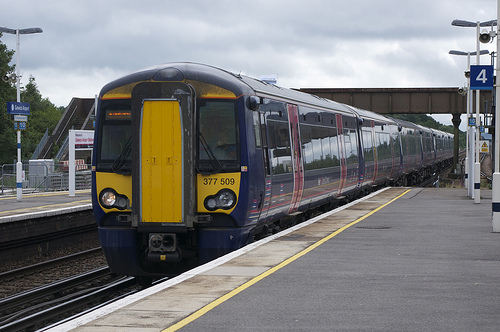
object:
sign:
[6, 100, 32, 116]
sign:
[12, 114, 29, 123]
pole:
[12, 28, 24, 201]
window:
[264, 117, 297, 178]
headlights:
[100, 190, 118, 208]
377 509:
[200, 176, 238, 186]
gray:
[390, 241, 493, 330]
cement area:
[163, 186, 499, 331]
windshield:
[194, 97, 243, 173]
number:
[229, 177, 236, 186]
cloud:
[0, 0, 499, 107]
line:
[160, 187, 414, 332]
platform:
[0, 187, 99, 226]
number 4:
[474, 67, 489, 84]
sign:
[468, 63, 495, 91]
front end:
[88, 59, 256, 278]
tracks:
[0, 263, 140, 332]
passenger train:
[89, 59, 458, 289]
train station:
[31, 186, 500, 331]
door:
[136, 96, 191, 224]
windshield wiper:
[198, 131, 222, 173]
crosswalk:
[33, 184, 500, 331]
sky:
[0, 0, 499, 111]